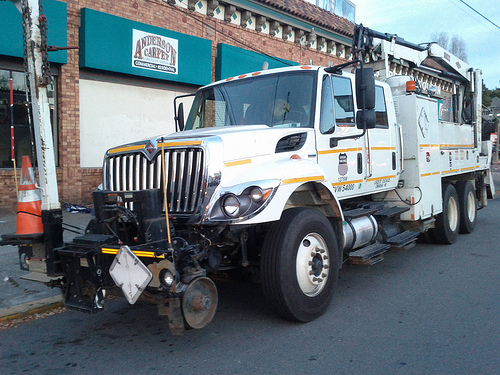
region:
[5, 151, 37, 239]
orange and white traffic cone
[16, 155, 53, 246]
partially crushed traffic cone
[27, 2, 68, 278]
tree near the street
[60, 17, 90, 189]
brick facade on a building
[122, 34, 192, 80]
sign for a business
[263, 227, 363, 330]
large truck tire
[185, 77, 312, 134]
windshield on a large truck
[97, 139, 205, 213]
front grill on a large truck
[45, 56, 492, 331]
large truck parked on the street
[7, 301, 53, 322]
curb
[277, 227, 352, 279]
wheel of white truck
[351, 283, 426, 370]
road that truck is on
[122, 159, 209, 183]
grill of truck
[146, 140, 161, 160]
logo of white truck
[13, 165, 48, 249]
cone attached to truck front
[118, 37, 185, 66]
logo of carpet place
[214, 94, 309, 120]
window of truck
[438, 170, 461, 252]
back wheel of truck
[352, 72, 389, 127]
side view mirror of truck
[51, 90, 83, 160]
brick wall of building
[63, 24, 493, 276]
a big truck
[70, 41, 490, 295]
a white truck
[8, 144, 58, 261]
an orange and white cone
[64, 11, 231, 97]
a store sign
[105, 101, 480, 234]
a truck with yellow stripes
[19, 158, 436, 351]
a truck with railroad wheels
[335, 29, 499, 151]
a truck with a bucket lift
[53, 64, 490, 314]
a truck parked on the street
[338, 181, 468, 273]
steps to reach the into the truck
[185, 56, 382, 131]
a big front window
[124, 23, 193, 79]
white Anderson Carpet store sign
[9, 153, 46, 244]
orange cones with white stripe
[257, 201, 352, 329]
large wheel on a truck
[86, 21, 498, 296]
white construction truck with yellow stripes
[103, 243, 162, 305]
white diamond with silver border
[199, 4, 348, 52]
ornate cornices with blue diamonds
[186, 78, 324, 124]
tinted truck windshield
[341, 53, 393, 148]
large side view mirror on a truck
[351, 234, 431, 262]
black step to enter truck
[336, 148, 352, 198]
emblem on the side of a truck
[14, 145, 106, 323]
Orange and white cone near side of road.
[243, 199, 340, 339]
Truck has black tires.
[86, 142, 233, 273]
Large metal grate on front of truck.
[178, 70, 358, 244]
Truck is mostly white in color.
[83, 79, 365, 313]
Truck is parked in front of building.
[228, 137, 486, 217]
Yellow stripe on side of truck.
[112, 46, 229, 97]
White sign with red writing on building.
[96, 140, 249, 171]
Yellow stripe on front of truck.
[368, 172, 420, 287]
Steps to get up into the truck.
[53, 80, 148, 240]
Brown bricks on building.